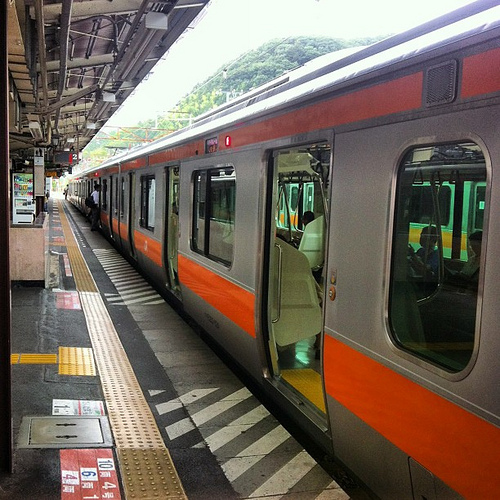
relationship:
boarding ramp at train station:
[53, 195, 193, 499] [2, 0, 192, 497]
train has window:
[56, 31, 489, 498] [381, 133, 486, 377]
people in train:
[416, 207, 491, 309] [334, 131, 487, 473]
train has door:
[56, 31, 489, 498] [251, 135, 339, 456]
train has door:
[56, 31, 489, 498] [158, 160, 188, 306]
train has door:
[56, 31, 489, 498] [121, 168, 140, 256]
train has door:
[56, 31, 489, 498] [99, 173, 116, 240]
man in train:
[80, 97, 422, 238] [56, 31, 489, 498]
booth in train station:
[8, 150, 58, 293] [15, 135, 419, 496]